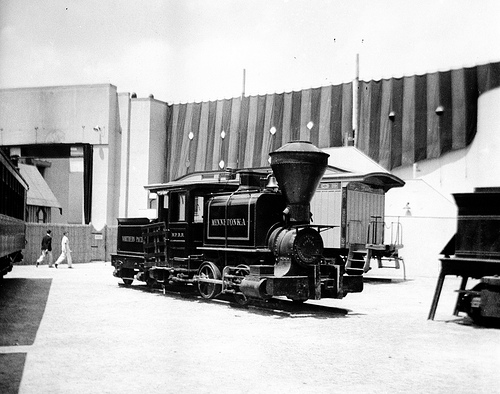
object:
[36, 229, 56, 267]
man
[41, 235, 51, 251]
coat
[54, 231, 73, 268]
peopel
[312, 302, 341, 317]
shadows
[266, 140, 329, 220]
stack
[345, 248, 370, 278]
steps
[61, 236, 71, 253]
shirt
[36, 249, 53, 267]
pants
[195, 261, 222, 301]
wheel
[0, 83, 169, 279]
building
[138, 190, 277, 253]
cab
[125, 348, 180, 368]
ground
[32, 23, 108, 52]
sky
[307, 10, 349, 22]
clouds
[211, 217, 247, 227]
lettering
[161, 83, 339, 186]
fence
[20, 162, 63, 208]
tent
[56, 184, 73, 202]
wall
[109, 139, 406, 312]
locomotive